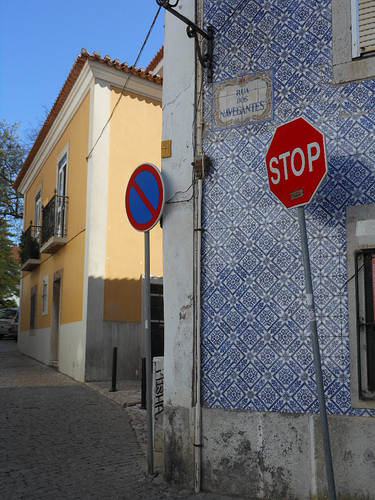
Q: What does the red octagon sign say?
A: Stop.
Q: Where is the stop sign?
A: In front of the house.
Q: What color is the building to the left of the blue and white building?
A: Yellow.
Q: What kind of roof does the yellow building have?
A: Clay tile.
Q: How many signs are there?
A: 2.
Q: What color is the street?
A: Gray.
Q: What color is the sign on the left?
A: Blue and red.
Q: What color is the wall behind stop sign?
A: Blue and white.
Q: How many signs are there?
A: 2.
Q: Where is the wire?
A: Hanging between buildings.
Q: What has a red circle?
A: Sign on left.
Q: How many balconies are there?
A: 2.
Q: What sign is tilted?
A: Stop.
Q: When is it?
A: Daytime.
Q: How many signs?
A: 2.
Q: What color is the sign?
A: Red.